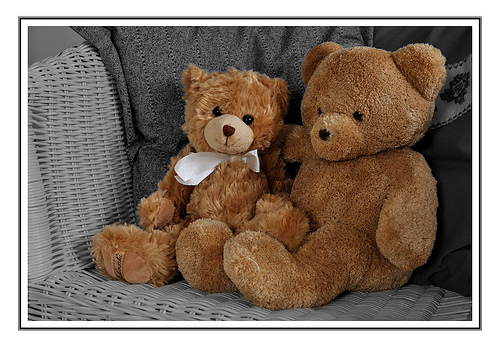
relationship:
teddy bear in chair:
[91, 65, 294, 293] [28, 27, 471, 321]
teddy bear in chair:
[177, 42, 448, 309] [28, 27, 471, 321]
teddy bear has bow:
[91, 65, 294, 293] [173, 149, 259, 186]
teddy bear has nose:
[91, 65, 294, 293] [223, 125, 234, 135]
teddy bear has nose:
[177, 42, 448, 309] [320, 129, 329, 139]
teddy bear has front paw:
[91, 65, 294, 293] [152, 198, 175, 226]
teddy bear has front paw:
[177, 42, 448, 309] [377, 232, 429, 269]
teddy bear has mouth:
[91, 65, 294, 293] [215, 138, 239, 146]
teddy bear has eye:
[91, 65, 294, 293] [212, 107, 222, 117]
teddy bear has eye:
[91, 65, 294, 293] [243, 115, 253, 123]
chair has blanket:
[28, 27, 471, 321] [70, 25, 372, 228]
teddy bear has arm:
[91, 65, 294, 293] [158, 143, 196, 208]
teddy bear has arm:
[177, 42, 448, 309] [277, 123, 308, 163]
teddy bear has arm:
[177, 42, 448, 309] [386, 151, 437, 238]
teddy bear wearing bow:
[91, 65, 294, 293] [173, 149, 259, 186]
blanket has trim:
[373, 26, 471, 297] [426, 53, 470, 130]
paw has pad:
[91, 224, 168, 285] [101, 247, 149, 284]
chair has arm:
[28, 27, 471, 321] [27, 40, 138, 283]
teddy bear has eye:
[177, 42, 448, 309] [318, 108, 322, 114]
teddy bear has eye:
[177, 42, 448, 309] [355, 110, 363, 119]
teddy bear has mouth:
[177, 42, 448, 309] [337, 148, 353, 161]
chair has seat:
[28, 27, 471, 321] [36, 264, 471, 321]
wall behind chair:
[29, 26, 97, 65] [28, 27, 471, 321]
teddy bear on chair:
[91, 65, 294, 293] [28, 27, 471, 321]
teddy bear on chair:
[177, 42, 448, 309] [28, 27, 471, 321]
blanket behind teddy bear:
[70, 25, 372, 228] [91, 65, 294, 293]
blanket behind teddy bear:
[373, 26, 471, 297] [177, 42, 448, 309]